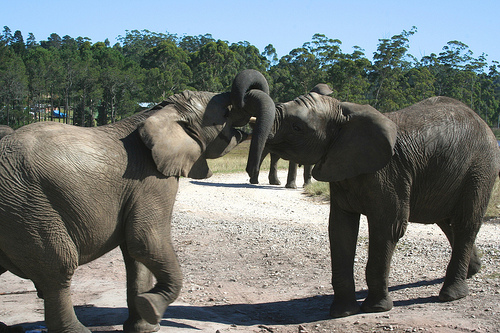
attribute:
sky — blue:
[322, 14, 364, 36]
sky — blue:
[1, 2, 499, 76]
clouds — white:
[328, 7, 399, 42]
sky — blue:
[4, 0, 496, 88]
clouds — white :
[373, 7, 470, 37]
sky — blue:
[366, 12, 441, 46]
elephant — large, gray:
[230, 68, 497, 315]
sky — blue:
[113, 11, 182, 31]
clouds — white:
[5, 5, 83, 30]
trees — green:
[35, 12, 499, 139]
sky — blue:
[262, 9, 469, 44]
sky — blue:
[14, 4, 484, 64]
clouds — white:
[213, 7, 319, 59]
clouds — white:
[304, 10, 380, 43]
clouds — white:
[276, 12, 369, 36]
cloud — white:
[350, 20, 379, 39]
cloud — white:
[267, 13, 306, 29]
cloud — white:
[306, 22, 337, 33]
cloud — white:
[204, 17, 244, 37]